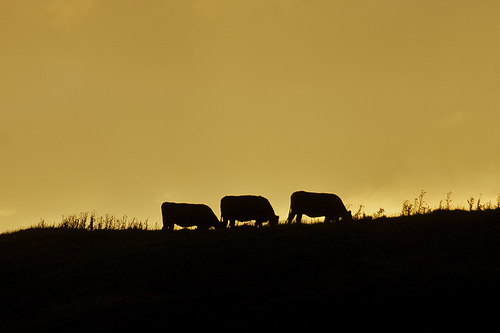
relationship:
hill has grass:
[1, 209, 498, 332] [63, 209, 150, 232]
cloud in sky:
[357, 190, 499, 214] [1, 2, 498, 230]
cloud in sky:
[2, 203, 156, 233] [1, 2, 498, 230]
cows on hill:
[160, 199, 228, 232] [1, 209, 498, 332]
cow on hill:
[221, 195, 280, 230] [1, 209, 498, 332]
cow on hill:
[288, 191, 353, 222] [1, 209, 498, 332]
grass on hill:
[63, 209, 150, 232] [1, 209, 498, 332]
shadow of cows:
[162, 191, 354, 231] [160, 189, 354, 231]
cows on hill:
[160, 189, 354, 231] [1, 209, 498, 332]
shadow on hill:
[162, 191, 354, 231] [1, 209, 498, 332]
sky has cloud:
[1, 2, 498, 230] [357, 190, 499, 214]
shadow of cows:
[162, 191, 354, 231] [160, 199, 228, 232]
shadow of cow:
[162, 191, 354, 231] [221, 195, 280, 230]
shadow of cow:
[162, 191, 354, 231] [288, 191, 353, 222]